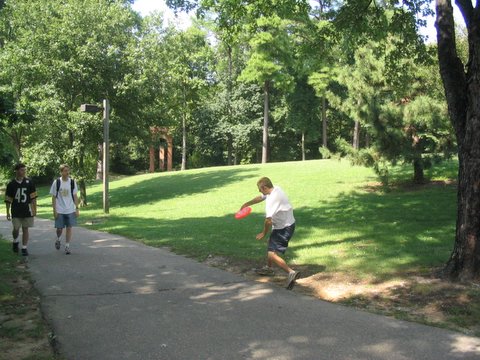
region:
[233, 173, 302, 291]
the man is holding a red frisbee.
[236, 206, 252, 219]
the frisbee is round in shape.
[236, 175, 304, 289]
the man is wearing a white shirt.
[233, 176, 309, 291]
the man is wearing tennis shoes.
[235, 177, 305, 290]
the man is wearing gray shorts.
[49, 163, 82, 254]
the man is carrying a back pack.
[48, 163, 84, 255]
the man is wearing blue jean shorts.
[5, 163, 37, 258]
the man is wearing a football jersey.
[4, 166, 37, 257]
the man is wearing tan shorts.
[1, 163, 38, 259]
the man is wearing black shoes.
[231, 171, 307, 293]
man wears a white top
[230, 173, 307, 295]
man holds a red frisbee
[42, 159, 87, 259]
person carry a backpack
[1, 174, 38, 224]
number 45 on a shirt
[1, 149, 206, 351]
two people on a road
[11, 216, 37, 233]
the pants are tan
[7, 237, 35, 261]
the shoes are brown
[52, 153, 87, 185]
the head of a man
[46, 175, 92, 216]
the arms of a man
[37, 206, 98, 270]
the legs of a man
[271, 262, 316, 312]
the foot of a man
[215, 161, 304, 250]
a man holding a frisbee.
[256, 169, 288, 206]
the hair of a man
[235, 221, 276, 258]
the hand of a man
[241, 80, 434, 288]
a man near a tree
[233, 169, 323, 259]
a man wearing a white shirt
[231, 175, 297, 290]
Man holding a red frisbee.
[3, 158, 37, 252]
Young man wearing a jersey.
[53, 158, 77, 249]
Guy in a white shirt with a backpack.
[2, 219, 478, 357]
Guys walking on the sidewalk.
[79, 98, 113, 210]
Pole with a street light.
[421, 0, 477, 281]
A large tree trunk.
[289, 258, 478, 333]
Light patch of dirt on the ground.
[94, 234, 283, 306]
Reflections and shadows on sidewalk.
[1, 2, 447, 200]
Tall green trees in background.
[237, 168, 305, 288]
Man wearing short sleeve white shirt throwing red disk.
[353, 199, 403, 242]
a shadow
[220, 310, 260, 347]
the sidewalk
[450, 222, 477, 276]
a tree trunk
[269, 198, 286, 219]
a white shirt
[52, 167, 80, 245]
a person walking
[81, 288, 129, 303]
crack in the sidewalk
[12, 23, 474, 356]
a scene at a park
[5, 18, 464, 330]
a scene outside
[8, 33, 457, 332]
a scene during the day time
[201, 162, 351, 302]
a person throwing a disc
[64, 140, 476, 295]
a green lawn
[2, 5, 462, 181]
some trees in area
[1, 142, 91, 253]
two people walking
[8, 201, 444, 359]
a gray sidewalk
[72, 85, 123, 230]
a light pole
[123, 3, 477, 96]
a white sky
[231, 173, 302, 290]
man getting ready to throw a frisbee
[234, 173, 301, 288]
man holding a red frisbee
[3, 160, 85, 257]
two men walking on a sidewalk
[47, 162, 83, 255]
man wearing black backpack straps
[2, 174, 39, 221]
black jersey with white numbers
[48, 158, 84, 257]
man wearing jean shorts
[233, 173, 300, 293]
man with frisbee wearing black shorts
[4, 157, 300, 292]
three men in a park